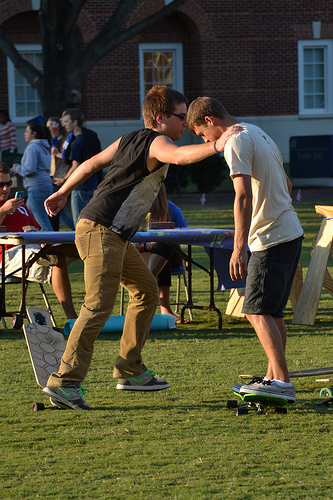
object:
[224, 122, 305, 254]
shirt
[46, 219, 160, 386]
pants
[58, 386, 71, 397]
logo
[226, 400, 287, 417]
skateboard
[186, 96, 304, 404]
man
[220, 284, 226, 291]
phone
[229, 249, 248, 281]
hand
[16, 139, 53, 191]
hoodie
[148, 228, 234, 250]
table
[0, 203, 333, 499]
grass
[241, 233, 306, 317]
shorts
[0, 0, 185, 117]
tree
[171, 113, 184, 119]
glasses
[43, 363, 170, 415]
shoes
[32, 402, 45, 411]
wheel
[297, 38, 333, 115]
window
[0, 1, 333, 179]
building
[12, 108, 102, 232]
people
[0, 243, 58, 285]
tablecloth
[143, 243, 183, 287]
paint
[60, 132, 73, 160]
vest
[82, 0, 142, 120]
wall